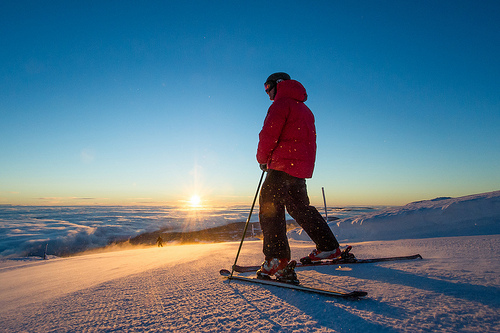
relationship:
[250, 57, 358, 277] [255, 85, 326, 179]
man in jacket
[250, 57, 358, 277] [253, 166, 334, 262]
man wearing pants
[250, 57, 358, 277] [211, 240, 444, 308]
man on skis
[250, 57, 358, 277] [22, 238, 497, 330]
man on snow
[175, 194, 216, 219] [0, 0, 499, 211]
sun in sky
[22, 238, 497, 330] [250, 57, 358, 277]
snow beneath man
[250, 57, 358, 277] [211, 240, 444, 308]
man wearing skis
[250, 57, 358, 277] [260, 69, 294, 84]
man in helmet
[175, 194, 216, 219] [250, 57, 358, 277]
sun behind man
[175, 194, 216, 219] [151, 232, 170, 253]
sun behind person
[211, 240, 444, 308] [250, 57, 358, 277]
skis underneath man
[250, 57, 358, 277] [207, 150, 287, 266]
man holding poles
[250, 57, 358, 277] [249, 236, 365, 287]
man in boots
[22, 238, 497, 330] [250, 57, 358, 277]
snow surrounding man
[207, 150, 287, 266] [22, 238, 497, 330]
poles in snow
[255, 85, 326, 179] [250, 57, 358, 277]
jacket on man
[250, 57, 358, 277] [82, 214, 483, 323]
man on mountain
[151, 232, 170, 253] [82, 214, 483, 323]
person on mountain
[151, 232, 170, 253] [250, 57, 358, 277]
person in front of man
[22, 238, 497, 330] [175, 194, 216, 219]
snow reflecting sun